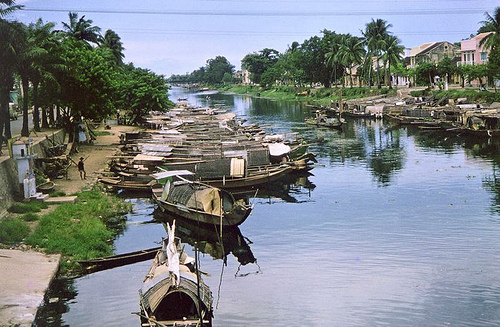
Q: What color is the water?
A: Blue.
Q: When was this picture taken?
A: Daytime.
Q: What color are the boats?
A: Brown.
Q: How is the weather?
A: Clear.